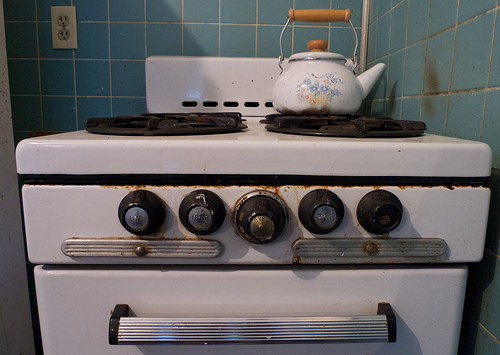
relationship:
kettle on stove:
[268, 3, 386, 120] [51, 105, 441, 295]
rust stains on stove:
[108, 178, 397, 198] [51, 105, 441, 295]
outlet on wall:
[49, 4, 83, 53] [96, 9, 253, 90]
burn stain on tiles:
[419, 48, 449, 115] [369, 6, 498, 118]